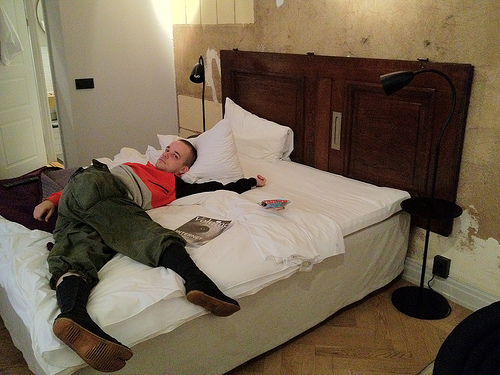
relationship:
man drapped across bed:
[32, 140, 266, 374] [1, 141, 412, 374]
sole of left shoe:
[53, 319, 133, 373] [54, 276, 127, 349]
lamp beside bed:
[380, 66, 463, 320] [1, 141, 412, 374]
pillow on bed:
[223, 98, 294, 162] [1, 141, 412, 374]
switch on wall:
[76, 79, 94, 89] [43, 0, 180, 168]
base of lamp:
[389, 286, 450, 320] [380, 66, 463, 320]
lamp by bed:
[380, 66, 463, 320] [1, 141, 412, 374]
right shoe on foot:
[158, 242, 240, 317] [187, 289, 241, 320]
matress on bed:
[285, 163, 413, 239] [1, 141, 412, 374]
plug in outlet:
[432, 255, 451, 279] [431, 269, 438, 277]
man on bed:
[32, 140, 266, 374] [1, 141, 412, 374]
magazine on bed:
[170, 214, 233, 249] [1, 141, 412, 374]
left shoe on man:
[54, 276, 127, 349] [32, 140, 266, 374]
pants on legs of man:
[48, 164, 188, 288] [32, 140, 266, 374]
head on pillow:
[154, 140, 196, 175] [181, 119, 244, 185]